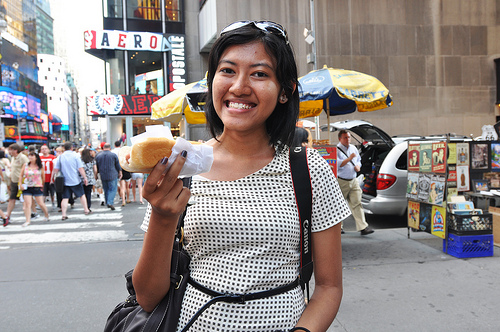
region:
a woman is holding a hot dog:
[102, 0, 342, 331]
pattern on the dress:
[205, 231, 275, 272]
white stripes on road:
[1, 220, 126, 255]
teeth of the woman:
[222, 100, 254, 112]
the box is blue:
[440, 233, 489, 256]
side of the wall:
[417, 29, 457, 83]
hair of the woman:
[264, 58, 299, 145]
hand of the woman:
[145, 173, 190, 223]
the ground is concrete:
[402, 291, 429, 313]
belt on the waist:
[188, 273, 301, 303]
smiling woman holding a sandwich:
[102, 17, 349, 328]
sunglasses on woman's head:
[215, 15, 285, 30]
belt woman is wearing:
[182, 272, 299, 327]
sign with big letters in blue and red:
[81, 26, 161, 46]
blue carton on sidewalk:
[445, 231, 490, 256]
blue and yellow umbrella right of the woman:
[295, 61, 390, 113]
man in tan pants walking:
[335, 126, 375, 232]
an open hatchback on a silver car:
[320, 112, 392, 207]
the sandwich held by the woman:
[107, 125, 212, 171]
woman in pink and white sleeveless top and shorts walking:
[16, 148, 48, 226]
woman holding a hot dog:
[128, 18, 350, 329]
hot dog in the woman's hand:
[115, 137, 198, 174]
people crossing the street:
[1, 138, 143, 228]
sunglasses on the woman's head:
[218, 19, 287, 45]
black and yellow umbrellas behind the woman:
[151, 61, 391, 121]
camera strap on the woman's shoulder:
[288, 140, 313, 285]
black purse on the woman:
[101, 170, 191, 330]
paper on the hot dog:
[128, 123, 213, 175]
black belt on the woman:
[180, 270, 302, 330]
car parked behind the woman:
[321, 115, 471, 217]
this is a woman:
[97, 18, 396, 330]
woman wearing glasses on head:
[197, 1, 293, 58]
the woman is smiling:
[216, 87, 276, 120]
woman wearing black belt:
[166, 270, 313, 322]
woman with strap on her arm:
[265, 142, 347, 284]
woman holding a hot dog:
[102, 104, 251, 236]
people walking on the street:
[6, 115, 128, 229]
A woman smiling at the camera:
[131, 20, 347, 330]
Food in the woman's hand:
[122, 135, 212, 176]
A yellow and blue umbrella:
[291, 67, 393, 119]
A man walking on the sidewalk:
[329, 130, 376, 234]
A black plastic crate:
[442, 207, 494, 234]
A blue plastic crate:
[440, 229, 494, 258]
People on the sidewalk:
[5, 139, 119, 231]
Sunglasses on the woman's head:
[220, 17, 288, 44]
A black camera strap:
[287, 140, 318, 301]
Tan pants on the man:
[334, 175, 368, 232]